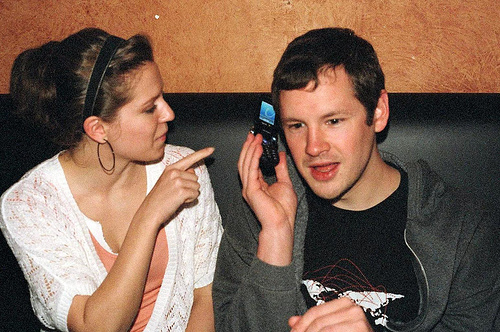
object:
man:
[210, 16, 500, 331]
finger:
[165, 147, 215, 171]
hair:
[8, 27, 152, 145]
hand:
[237, 125, 301, 229]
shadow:
[102, 168, 115, 175]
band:
[84, 35, 125, 123]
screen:
[259, 101, 276, 126]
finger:
[246, 143, 264, 196]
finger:
[241, 133, 263, 196]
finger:
[237, 125, 255, 182]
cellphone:
[251, 98, 281, 176]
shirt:
[90, 226, 168, 332]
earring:
[96, 138, 116, 171]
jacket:
[211, 150, 499, 332]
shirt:
[300, 162, 418, 327]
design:
[299, 257, 406, 326]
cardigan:
[0, 141, 226, 332]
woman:
[0, 26, 226, 332]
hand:
[129, 146, 217, 233]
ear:
[83, 115, 107, 144]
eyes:
[288, 123, 306, 130]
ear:
[374, 89, 390, 133]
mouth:
[307, 161, 342, 182]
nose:
[304, 125, 330, 158]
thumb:
[274, 150, 292, 187]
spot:
[154, 15, 160, 20]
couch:
[1, 88, 499, 329]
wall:
[0, 0, 500, 92]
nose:
[158, 100, 175, 124]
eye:
[325, 118, 347, 125]